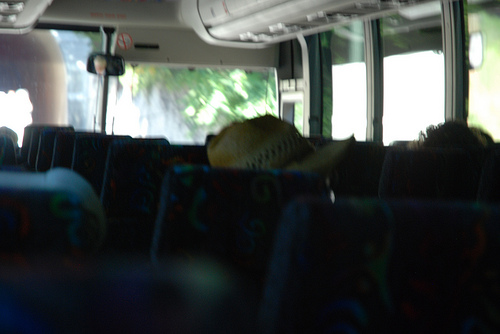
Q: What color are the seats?
A: Blue.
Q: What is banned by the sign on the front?
A: Smoking.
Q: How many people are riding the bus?
A: 2.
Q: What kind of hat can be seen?
A: Straw.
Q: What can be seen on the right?
A: Bus windows.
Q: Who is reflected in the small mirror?
A: Driver.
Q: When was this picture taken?
A: Late afternoon.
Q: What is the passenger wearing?
A: Hat.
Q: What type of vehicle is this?
A: Bus.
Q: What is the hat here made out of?
A: Straw.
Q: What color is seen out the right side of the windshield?
A: Green.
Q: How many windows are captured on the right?
A: Three.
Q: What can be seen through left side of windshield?
A: Tunnel.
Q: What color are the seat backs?
A: Blue.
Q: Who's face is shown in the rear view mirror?
A: Bus driver's face.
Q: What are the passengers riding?
A: A bus.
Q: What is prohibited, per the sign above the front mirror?
A: Smoking.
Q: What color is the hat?
A: Brown.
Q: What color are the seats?
A: Blue.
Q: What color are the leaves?
A: Green.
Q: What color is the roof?
A: White.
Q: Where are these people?
A: On a bus.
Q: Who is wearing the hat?
A: A lady.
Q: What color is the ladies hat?
A: Tan.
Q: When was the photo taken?
A: Daytime.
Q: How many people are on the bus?
A: 3.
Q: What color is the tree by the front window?
A: Green.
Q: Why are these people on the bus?
A: To go somewhere.